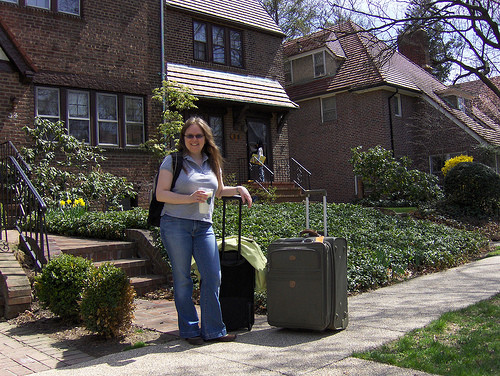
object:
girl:
[150, 113, 255, 345]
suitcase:
[263, 185, 351, 334]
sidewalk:
[21, 253, 499, 376]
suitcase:
[211, 192, 266, 333]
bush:
[79, 261, 137, 344]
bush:
[28, 246, 94, 326]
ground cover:
[19, 196, 492, 314]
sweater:
[187, 232, 266, 292]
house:
[1, 1, 308, 210]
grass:
[350, 291, 500, 375]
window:
[32, 84, 63, 148]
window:
[65, 86, 93, 144]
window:
[93, 90, 123, 148]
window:
[119, 93, 147, 145]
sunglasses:
[184, 132, 208, 139]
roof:
[167, 0, 287, 38]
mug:
[196, 186, 219, 216]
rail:
[0, 135, 51, 271]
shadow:
[41, 324, 196, 376]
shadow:
[235, 324, 343, 351]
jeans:
[159, 213, 228, 341]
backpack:
[145, 149, 187, 227]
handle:
[299, 183, 330, 236]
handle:
[218, 194, 244, 259]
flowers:
[59, 198, 66, 208]